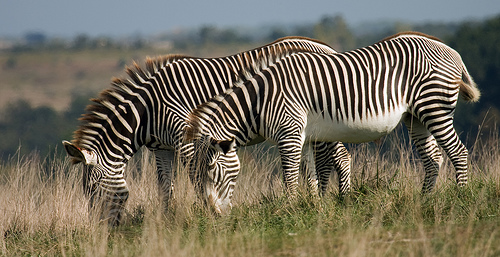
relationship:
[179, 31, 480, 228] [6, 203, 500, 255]
zebra in field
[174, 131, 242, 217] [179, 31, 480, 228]
head of zebra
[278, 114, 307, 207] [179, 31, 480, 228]
leg of zebra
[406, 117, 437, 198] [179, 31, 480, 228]
leg of zebra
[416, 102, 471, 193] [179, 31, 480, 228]
leg of zebra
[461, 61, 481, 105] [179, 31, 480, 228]
tail of zebra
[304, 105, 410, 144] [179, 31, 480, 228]
underside of zebra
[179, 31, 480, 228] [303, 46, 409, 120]
zebra has stripes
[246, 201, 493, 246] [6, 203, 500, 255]
grass in savannah